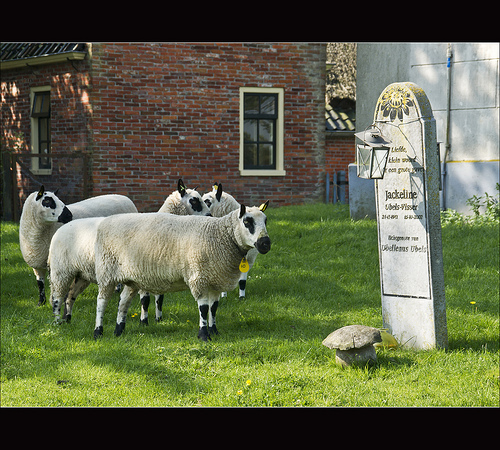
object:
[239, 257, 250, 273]
tag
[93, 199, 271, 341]
animal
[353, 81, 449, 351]
headstone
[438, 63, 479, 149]
trees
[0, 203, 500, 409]
area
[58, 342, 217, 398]
shadows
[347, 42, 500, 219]
building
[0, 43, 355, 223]
brick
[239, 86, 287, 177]
frame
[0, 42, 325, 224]
building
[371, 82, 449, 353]
stone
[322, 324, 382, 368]
grave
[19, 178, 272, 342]
sheep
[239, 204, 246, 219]
ears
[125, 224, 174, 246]
wool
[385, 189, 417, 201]
letter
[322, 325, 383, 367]
mushroom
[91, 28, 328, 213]
wall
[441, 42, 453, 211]
pole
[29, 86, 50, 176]
window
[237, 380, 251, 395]
flower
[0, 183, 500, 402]
grass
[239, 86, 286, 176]
window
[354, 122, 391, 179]
lamp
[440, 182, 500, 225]
bushes